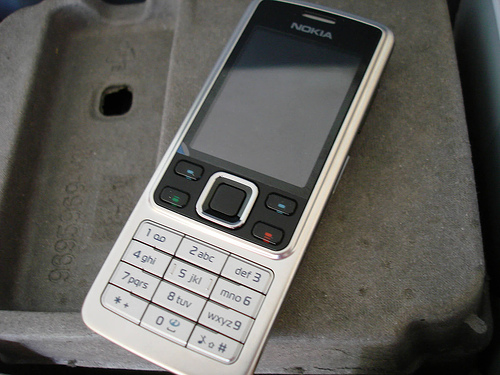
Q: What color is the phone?
A: White and black.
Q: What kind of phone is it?
A: Cell phone.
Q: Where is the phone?
A: On top of something.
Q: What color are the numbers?
A: Black.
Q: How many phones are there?
A: One.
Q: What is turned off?
A: The phone.